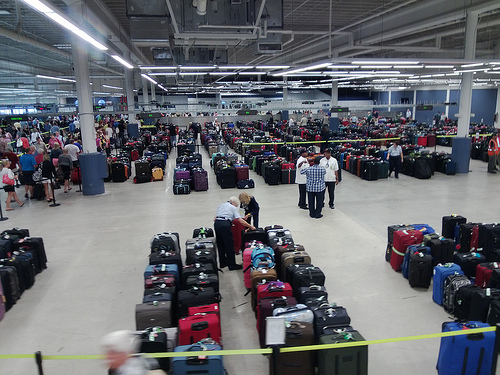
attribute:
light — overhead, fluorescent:
[110, 52, 136, 71]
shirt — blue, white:
[299, 164, 328, 192]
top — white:
[320, 155, 339, 182]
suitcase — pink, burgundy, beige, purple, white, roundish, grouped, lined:
[140, 271, 176, 297]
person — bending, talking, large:
[212, 193, 258, 270]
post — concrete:
[65, 6, 108, 198]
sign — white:
[264, 316, 288, 347]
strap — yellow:
[240, 137, 399, 149]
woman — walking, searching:
[386, 139, 406, 181]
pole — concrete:
[455, 7, 479, 171]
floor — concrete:
[1, 125, 499, 373]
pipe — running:
[164, 6, 266, 48]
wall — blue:
[374, 88, 499, 131]